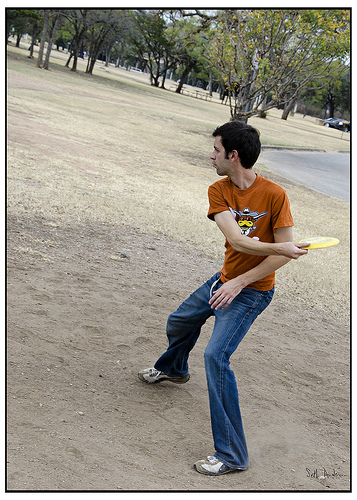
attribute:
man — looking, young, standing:
[138, 120, 310, 475]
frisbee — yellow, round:
[294, 235, 340, 251]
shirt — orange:
[207, 175, 294, 292]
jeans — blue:
[154, 272, 275, 470]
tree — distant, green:
[189, 35, 225, 97]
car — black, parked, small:
[325, 118, 353, 132]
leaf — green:
[303, 10, 309, 16]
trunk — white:
[35, 9, 45, 71]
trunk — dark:
[72, 38, 80, 75]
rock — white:
[78, 410, 88, 418]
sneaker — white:
[191, 452, 234, 477]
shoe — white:
[137, 366, 188, 386]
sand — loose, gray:
[7, 221, 352, 491]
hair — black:
[213, 120, 260, 171]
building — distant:
[113, 48, 208, 84]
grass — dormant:
[8, 41, 349, 317]